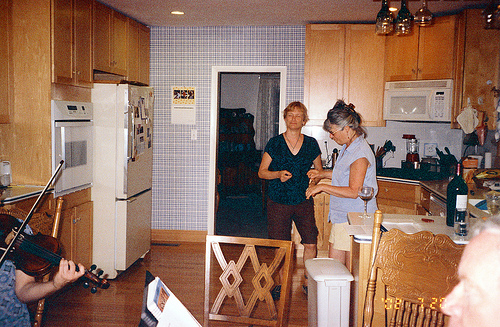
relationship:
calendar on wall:
[168, 81, 201, 128] [152, 25, 302, 228]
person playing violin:
[2, 206, 88, 325] [3, 216, 113, 302]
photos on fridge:
[132, 88, 151, 156] [94, 81, 155, 284]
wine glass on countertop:
[455, 203, 472, 238] [350, 210, 488, 242]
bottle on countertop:
[444, 159, 471, 230] [350, 210, 488, 242]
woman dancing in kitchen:
[312, 98, 381, 282] [10, 6, 481, 302]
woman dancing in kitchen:
[258, 99, 323, 289] [10, 6, 481, 302]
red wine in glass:
[361, 193, 371, 202] [358, 178, 377, 221]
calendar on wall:
[168, 84, 195, 125] [152, 25, 302, 228]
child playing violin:
[2, 214, 86, 324] [0, 215, 110, 295]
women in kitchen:
[258, 102, 384, 278] [10, 6, 481, 302]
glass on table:
[355, 185, 373, 221] [350, 201, 483, 258]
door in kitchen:
[215, 69, 297, 249] [10, 6, 481, 302]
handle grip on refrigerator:
[127, 108, 139, 167] [88, 78, 159, 271]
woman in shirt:
[258, 99, 323, 289] [263, 132, 315, 203]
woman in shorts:
[258, 99, 323, 289] [269, 200, 314, 244]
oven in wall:
[50, 97, 90, 193] [8, 4, 152, 286]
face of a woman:
[319, 123, 343, 149] [305, 98, 376, 188]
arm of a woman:
[313, 156, 382, 202] [312, 90, 393, 200]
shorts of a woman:
[325, 215, 386, 259] [313, 95, 394, 185]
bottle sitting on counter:
[444, 152, 474, 240] [376, 208, 496, 281]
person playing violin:
[2, 206, 88, 325] [1, 212, 143, 321]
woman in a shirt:
[317, 98, 393, 172] [333, 148, 373, 218]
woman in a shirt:
[258, 99, 323, 289] [264, 130, 334, 231]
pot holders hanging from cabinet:
[451, 99, 491, 149] [444, 14, 498, 144]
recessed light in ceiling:
[165, 6, 187, 26] [123, 3, 305, 34]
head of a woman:
[276, 98, 313, 138] [256, 88, 341, 269]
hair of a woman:
[286, 98, 307, 120] [267, 90, 332, 168]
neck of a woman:
[278, 123, 310, 144] [276, 96, 310, 146]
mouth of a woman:
[287, 115, 303, 133] [267, 98, 314, 155]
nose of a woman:
[289, 112, 303, 130] [270, 90, 322, 163]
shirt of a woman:
[256, 136, 338, 216] [267, 98, 314, 155]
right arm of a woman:
[257, 148, 294, 188] [267, 95, 321, 155]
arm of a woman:
[306, 156, 370, 198] [260, 96, 344, 182]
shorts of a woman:
[263, 197, 333, 267] [262, 90, 325, 170]